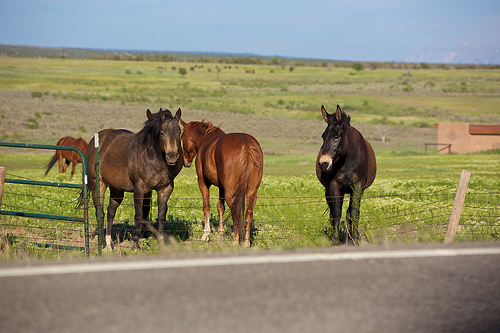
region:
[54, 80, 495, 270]
these are horses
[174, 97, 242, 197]
this horse is brown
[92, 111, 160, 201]
this horse is dark brown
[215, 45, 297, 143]
the field is brown and green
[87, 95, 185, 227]
brown mule in green field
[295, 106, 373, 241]
brown mule in green field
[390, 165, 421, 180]
short green and yellow grass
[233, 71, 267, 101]
short green and yellow grass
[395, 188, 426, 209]
short green and yellow grass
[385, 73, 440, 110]
short green and yellow grass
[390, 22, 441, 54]
white clouds in blue sky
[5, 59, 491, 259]
four horses in a corral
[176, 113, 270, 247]
horse is light brown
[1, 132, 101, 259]
a green fence on left side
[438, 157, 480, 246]
a pole on a fence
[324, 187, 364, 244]
front legs of a horse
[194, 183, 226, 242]
front legs of a horse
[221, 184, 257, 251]
back legs of a horse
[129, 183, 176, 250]
front legs of a horse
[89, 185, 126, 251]
back legs of a horse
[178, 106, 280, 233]
this is a horse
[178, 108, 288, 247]
the horse is brown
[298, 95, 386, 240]
the horse is dark brown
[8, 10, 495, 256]
a group of horse in a field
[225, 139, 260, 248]
brown tail on horse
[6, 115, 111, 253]
green rail next to horse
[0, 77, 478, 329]
horses facing a road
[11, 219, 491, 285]
white line on a road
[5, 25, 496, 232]
large field in the background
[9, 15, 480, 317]
a bright and sunny day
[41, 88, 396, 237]
Horses in a pin fenced in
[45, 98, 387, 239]
Horses in a pin fenced in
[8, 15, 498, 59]
a blue sky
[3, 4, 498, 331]
a scene of a pasture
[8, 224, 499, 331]
a gray street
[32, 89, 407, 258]
a group of horses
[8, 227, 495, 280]
a white line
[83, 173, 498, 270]
a gray fence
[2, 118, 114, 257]
a green gate door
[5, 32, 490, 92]
hills in the background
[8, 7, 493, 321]
a scene outside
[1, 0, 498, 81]
A clear sky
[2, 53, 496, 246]
The green pasture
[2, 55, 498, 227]
A green pasture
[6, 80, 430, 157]
The dirt patch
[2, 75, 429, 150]
A dirt patch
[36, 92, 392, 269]
The group of horses